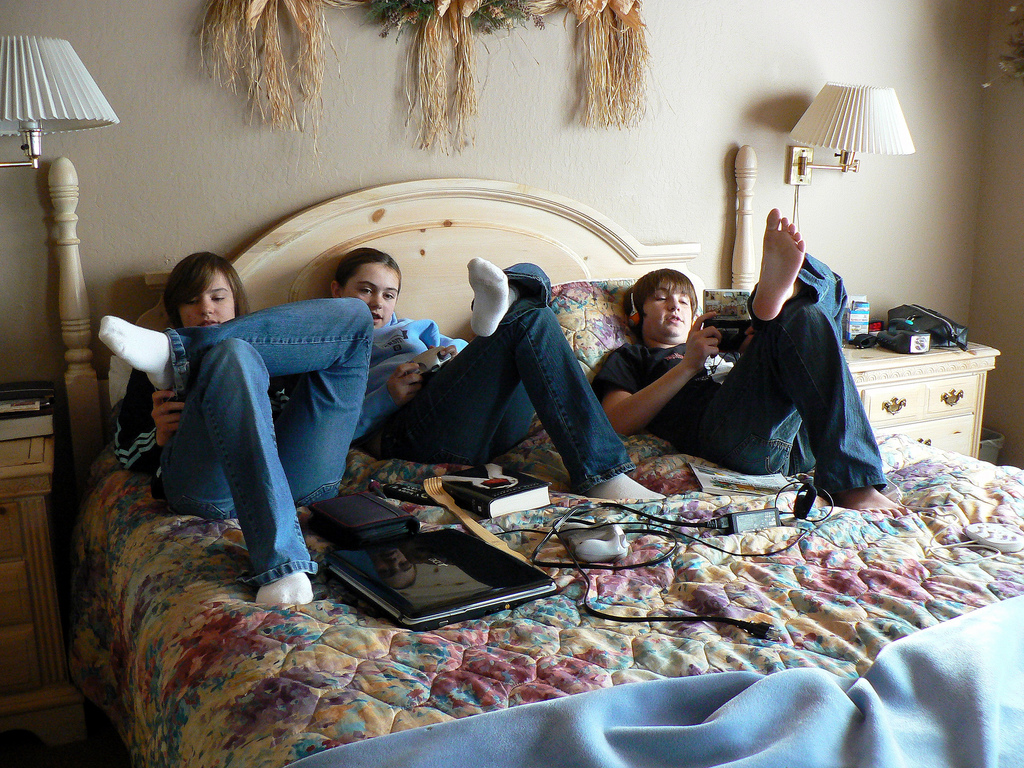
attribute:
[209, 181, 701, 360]
headboard — wooden, light beige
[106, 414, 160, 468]
stripes — blue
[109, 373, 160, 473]
sleeve — black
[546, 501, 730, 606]
control — black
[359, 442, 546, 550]
buttons — grey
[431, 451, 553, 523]
book — black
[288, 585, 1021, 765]
blanket — blue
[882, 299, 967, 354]
bag — black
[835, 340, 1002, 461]
table — light beige, wooden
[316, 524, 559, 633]
laptop — black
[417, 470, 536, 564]
back scratcher — brown, wooden